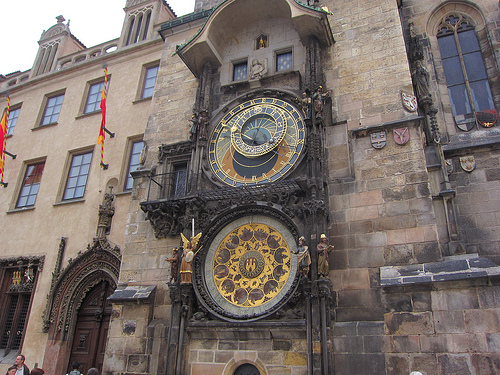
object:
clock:
[197, 96, 306, 193]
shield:
[367, 131, 389, 150]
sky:
[0, 0, 197, 77]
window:
[140, 85, 157, 100]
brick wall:
[99, 0, 499, 374]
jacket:
[8, 362, 31, 375]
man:
[6, 352, 35, 374]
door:
[67, 278, 107, 374]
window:
[273, 50, 294, 72]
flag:
[0, 95, 11, 183]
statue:
[246, 58, 267, 81]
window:
[456, 48, 487, 84]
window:
[140, 76, 158, 91]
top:
[29, 14, 88, 77]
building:
[100, 0, 500, 374]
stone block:
[346, 188, 387, 208]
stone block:
[352, 229, 386, 249]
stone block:
[411, 239, 442, 263]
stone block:
[354, 319, 387, 338]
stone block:
[403, 226, 425, 244]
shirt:
[14, 366, 24, 375]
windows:
[67, 152, 83, 169]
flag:
[96, 66, 108, 172]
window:
[72, 186, 85, 201]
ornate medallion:
[209, 222, 293, 309]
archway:
[37, 235, 123, 374]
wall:
[0, 36, 163, 374]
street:
[4, 349, 495, 373]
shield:
[187, 200, 305, 325]